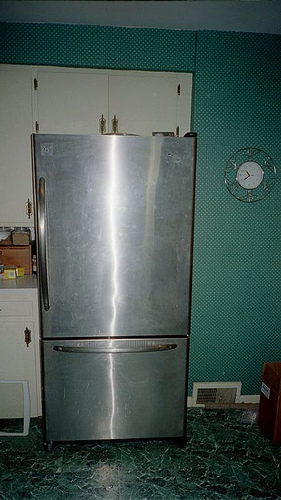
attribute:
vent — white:
[191, 380, 243, 406]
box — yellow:
[1, 266, 18, 279]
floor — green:
[2, 443, 280, 499]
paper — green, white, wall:
[196, 272, 271, 415]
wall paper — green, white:
[1, 21, 278, 386]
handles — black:
[243, 169, 252, 181]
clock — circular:
[220, 144, 279, 204]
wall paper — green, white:
[0, 0, 279, 409]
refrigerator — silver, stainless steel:
[27, 127, 189, 442]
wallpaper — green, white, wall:
[0, 23, 280, 403]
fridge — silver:
[19, 118, 198, 399]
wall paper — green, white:
[187, 36, 276, 400]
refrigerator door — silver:
[33, 132, 191, 334]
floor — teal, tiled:
[6, 447, 276, 493]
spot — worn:
[89, 465, 121, 487]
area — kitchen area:
[3, 8, 225, 265]